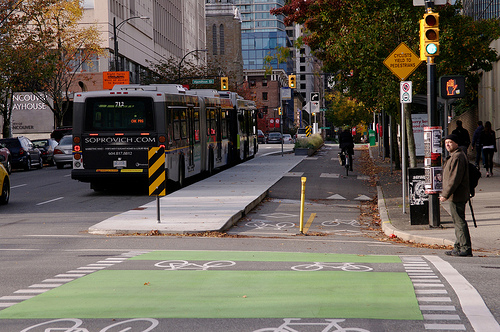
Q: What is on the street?
A: A bus.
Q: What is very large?
A: The bus.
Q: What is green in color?
A: Stop lights.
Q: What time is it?
A: Afternoon.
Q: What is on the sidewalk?
A: A tree.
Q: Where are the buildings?
A: In the back.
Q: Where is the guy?
A: On the street.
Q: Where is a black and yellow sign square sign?
A: Middle of sidewalk.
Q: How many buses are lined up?
A: Three.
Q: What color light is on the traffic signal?
A: Green.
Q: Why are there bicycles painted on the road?
A: Bicycle lane.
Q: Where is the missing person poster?
A: On the traffic signal pole.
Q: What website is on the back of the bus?
A: Soprovich.com.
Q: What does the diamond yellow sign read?
A: Cyclists yield to pedestrians.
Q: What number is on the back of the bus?
A: Seven hundred and twelve.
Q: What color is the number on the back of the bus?
A: White.